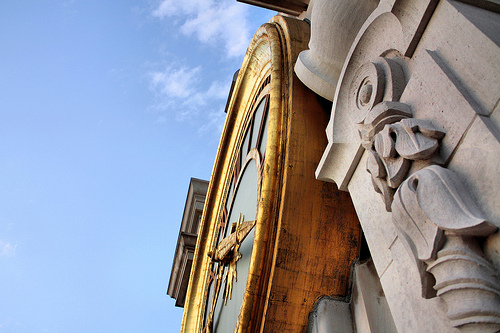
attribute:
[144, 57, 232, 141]
clouds — white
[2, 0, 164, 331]
sky —  with no clouds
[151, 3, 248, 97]
clouds —  white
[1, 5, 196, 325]
sky —  blue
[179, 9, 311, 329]
clock —  yellow,  golden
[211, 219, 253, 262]
clock hand —  gold,  clock's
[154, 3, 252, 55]
clouds — white,  small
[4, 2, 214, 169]
sky —  blue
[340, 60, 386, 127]
design —  cement,  a circle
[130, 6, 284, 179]
clouds — white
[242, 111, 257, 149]
gold line —  gold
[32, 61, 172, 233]
sky —  blue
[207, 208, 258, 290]
hands — brass-colored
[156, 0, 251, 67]
cloud —  white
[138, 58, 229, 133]
cloud —  white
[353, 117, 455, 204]
wave design —  small,  a wave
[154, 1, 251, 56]
cloud —  white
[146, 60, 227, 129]
cloud —  white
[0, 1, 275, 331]
sky —  bright blue, clear, Blue,  blue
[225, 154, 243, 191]
number —  numeric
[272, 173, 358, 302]
side —   rim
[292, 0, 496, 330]
building —  concrete,  tan and white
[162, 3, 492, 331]
building — concrete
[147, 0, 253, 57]
clouds —  white, white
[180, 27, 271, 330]
face —  clock's